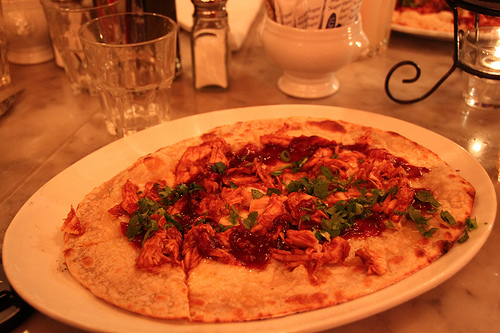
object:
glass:
[39, 1, 132, 101]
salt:
[184, 0, 237, 93]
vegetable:
[439, 206, 460, 229]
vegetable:
[278, 149, 294, 163]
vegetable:
[249, 185, 266, 201]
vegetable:
[411, 188, 443, 212]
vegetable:
[456, 230, 471, 243]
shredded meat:
[133, 228, 181, 270]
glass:
[72, 15, 180, 139]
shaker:
[189, 0, 231, 95]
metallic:
[384, 3, 500, 110]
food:
[54, 111, 479, 323]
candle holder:
[384, 51, 461, 106]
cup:
[260, 16, 367, 100]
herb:
[317, 197, 367, 227]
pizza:
[61, 115, 476, 323]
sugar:
[267, 0, 362, 31]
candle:
[479, 36, 500, 88]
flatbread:
[33, 103, 479, 309]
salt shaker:
[187, 0, 231, 92]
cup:
[2, 0, 54, 64]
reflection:
[460, 122, 494, 157]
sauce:
[255, 149, 290, 164]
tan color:
[63, 233, 127, 305]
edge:
[322, 239, 491, 331]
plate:
[0, 104, 495, 331]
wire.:
[380, 48, 463, 106]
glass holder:
[453, 14, 499, 108]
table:
[0, 10, 500, 331]